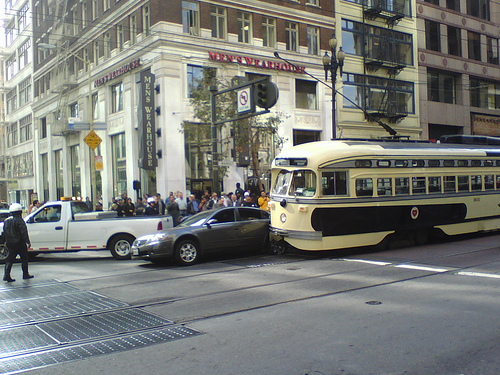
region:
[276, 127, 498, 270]
yellow trolley on the street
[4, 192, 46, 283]
police officer in the street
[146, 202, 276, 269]
car on the street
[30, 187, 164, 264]
white pick up truck on the street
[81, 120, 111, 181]
street sign on a pole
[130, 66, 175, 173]
sign on the side of the building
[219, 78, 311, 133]
stoplight over the street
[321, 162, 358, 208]
window on the bus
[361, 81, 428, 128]
fire escape on the building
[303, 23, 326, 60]
window on the building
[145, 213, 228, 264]
A car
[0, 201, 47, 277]
A person standing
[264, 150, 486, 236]
a yellow and black bus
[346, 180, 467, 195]
windows on the bus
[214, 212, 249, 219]
windows on the bus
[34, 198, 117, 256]
a white truck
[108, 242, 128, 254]
tire on the truck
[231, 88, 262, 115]
a street sign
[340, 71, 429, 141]
a yellow building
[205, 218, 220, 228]
mirror on the car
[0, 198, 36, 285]
policeman with a white helmet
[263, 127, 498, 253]
yellow and black colored bus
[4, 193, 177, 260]
white colored pickup truck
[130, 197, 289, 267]
silver car on the street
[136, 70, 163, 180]
sign for mens wearhouse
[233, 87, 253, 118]
no turn sign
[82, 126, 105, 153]
yellow diamond shaped street sign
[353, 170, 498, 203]
row of windows on a bus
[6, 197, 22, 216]
officer's white helmet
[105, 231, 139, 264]
rear wheel of white truck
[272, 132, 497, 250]
A white and black bus.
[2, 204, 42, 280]
A policeman walking on street.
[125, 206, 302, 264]
A crashed gray car.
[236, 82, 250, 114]
A no turn traffic sign.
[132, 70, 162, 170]
A Men's Warehouse Sign.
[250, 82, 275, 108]
A black traffic light.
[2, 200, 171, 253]
A white pickup truck.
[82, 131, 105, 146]
A yellow diamond sign.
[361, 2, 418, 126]
A fire escape on a building.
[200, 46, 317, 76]
A red store sign.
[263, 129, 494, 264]
a cream colored trolley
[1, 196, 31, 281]
a police officer in street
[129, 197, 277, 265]
a grey car in street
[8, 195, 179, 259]
a white truck in street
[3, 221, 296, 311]
a set of trolley tracks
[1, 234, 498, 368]
a set of trolley tracks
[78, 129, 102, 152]
a yellow traffic sign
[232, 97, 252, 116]
a no turn sign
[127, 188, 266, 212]
pedestrians on sidewalk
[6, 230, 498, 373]
a paved city street